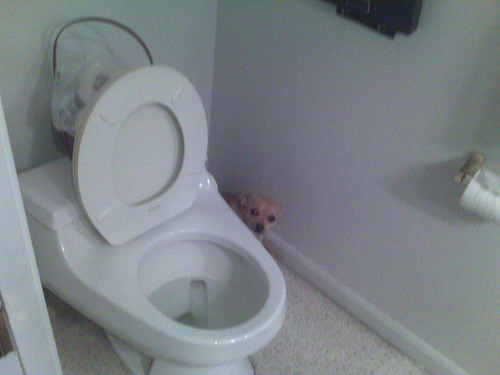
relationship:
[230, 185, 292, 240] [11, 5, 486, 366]
dog hiding in bathroom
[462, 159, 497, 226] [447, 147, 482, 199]
toilet paper on holder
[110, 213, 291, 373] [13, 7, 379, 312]
toilet in bathroom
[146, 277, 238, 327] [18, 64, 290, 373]
water inside of toilet bowl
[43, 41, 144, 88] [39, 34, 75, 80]
toilet paper inside of plastic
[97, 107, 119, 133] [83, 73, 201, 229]
stopper on bottom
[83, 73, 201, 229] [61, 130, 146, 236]
bottom of toilet seat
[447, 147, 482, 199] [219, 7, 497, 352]
holder attached to wall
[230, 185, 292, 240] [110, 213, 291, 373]
dog behind toilet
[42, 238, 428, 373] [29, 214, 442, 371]
carpet covering ground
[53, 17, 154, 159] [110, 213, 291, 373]
basket behind toilet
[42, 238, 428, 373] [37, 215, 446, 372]
carpet on floor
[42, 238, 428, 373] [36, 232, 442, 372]
carpet on floor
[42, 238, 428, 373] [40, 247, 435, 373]
carpet on floor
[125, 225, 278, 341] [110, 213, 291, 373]
rim of toilet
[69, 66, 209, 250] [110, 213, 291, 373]
lid of toilet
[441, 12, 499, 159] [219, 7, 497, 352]
shadow on wall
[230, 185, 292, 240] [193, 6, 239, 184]
dog in corner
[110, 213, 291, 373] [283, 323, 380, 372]
toilet on floor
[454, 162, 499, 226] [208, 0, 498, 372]
roll on wall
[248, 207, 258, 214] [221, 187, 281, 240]
eye of dog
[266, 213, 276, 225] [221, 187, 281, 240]
eye of dog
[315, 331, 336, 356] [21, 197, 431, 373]
patch on floor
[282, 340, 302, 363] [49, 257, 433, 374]
patch on floor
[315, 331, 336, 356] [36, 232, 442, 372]
patch on floor